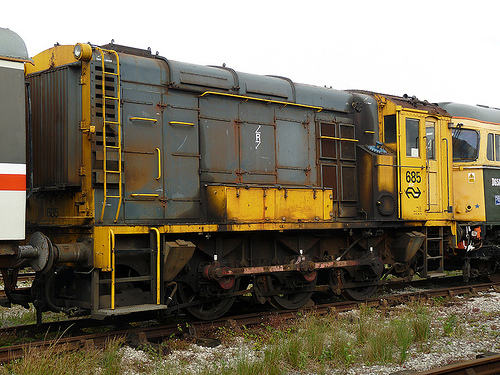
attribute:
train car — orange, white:
[2, 25, 52, 252]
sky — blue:
[321, 4, 442, 54]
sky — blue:
[67, 7, 498, 36]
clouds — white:
[1, 2, 499, 105]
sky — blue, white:
[0, 0, 497, 122]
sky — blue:
[0, 4, 498, 109]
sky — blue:
[25, 4, 492, 97]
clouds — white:
[230, 4, 500, 91]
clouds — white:
[374, 9, 472, 58]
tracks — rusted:
[10, 307, 247, 374]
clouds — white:
[304, 29, 408, 77]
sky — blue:
[2, 1, 499, 81]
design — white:
[236, 103, 281, 163]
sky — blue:
[314, 32, 480, 75]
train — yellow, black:
[25, 37, 458, 324]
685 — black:
[404, 167, 423, 182]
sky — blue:
[3, 6, 480, 76]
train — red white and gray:
[0, 26, 32, 243]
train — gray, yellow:
[35, 59, 432, 330]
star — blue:
[469, 200, 484, 210]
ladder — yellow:
[94, 46, 121, 222]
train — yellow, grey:
[0, 29, 498, 321]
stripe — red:
[0, 174, 27, 191]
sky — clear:
[260, 19, 498, 104]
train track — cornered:
[405, 350, 499, 374]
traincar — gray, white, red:
[2, 26, 26, 286]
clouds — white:
[195, 1, 471, 86]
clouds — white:
[312, 1, 442, 69]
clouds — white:
[177, 2, 458, 42]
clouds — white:
[354, 21, 434, 73]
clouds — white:
[292, 17, 403, 77]